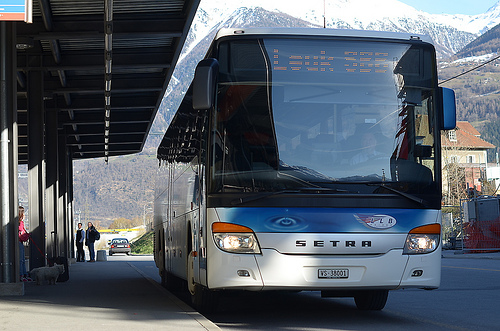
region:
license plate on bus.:
[312, 265, 349, 280]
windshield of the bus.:
[295, 110, 362, 146]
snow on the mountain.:
[368, 7, 407, 17]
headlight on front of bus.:
[215, 225, 256, 255]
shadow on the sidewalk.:
[89, 267, 139, 312]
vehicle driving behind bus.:
[110, 233, 133, 255]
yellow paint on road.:
[456, 263, 493, 273]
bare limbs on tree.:
[453, 151, 464, 195]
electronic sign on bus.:
[265, 48, 389, 70]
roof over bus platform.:
[75, 9, 138, 120]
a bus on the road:
[145, 11, 468, 324]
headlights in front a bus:
[201, 210, 446, 268]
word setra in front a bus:
[266, 225, 402, 261]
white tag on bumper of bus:
[296, 254, 370, 287]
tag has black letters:
[311, 259, 360, 282]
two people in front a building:
[68, 214, 104, 266]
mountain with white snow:
[199, 0, 489, 33]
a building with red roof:
[441, 114, 498, 184]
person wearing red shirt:
[8, 200, 50, 279]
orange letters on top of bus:
[248, 40, 401, 85]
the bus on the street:
[171, 20, 457, 327]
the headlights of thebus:
[201, 215, 462, 270]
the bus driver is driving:
[343, 125, 395, 170]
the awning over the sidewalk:
[39, 3, 163, 163]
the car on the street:
[98, 227, 133, 261]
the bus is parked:
[183, 19, 484, 320]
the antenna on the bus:
[308, 0, 337, 30]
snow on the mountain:
[241, 2, 499, 28]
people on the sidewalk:
[71, 212, 102, 272]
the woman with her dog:
[16, 208, 73, 299]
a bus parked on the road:
[112, 4, 453, 324]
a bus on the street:
[152, 20, 447, 328]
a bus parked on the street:
[98, 20, 495, 317]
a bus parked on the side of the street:
[112, 25, 446, 329]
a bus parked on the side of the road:
[129, 6, 490, 313]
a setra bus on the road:
[108, 11, 437, 328]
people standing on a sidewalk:
[55, 193, 128, 283]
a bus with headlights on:
[103, 23, 497, 328]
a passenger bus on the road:
[127, 14, 474, 330]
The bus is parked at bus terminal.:
[186, 41, 460, 328]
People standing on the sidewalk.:
[77, 212, 101, 257]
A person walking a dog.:
[8, 209, 70, 293]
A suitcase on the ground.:
[51, 225, 81, 278]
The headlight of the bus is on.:
[223, 216, 455, 255]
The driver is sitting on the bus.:
[340, 100, 390, 180]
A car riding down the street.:
[107, 227, 159, 263]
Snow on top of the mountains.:
[200, 11, 468, 55]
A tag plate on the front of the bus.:
[310, 263, 371, 276]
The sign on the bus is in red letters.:
[258, 42, 420, 77]